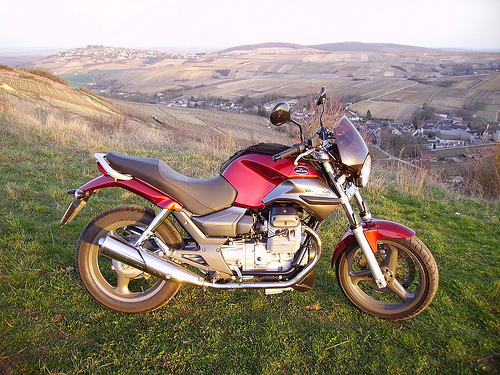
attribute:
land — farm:
[28, 45, 490, 152]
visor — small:
[330, 112, 369, 171]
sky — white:
[96, 0, 373, 71]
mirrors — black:
[269, 84, 327, 131]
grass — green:
[235, 307, 363, 358]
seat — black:
[106, 147, 238, 217]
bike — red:
[58, 85, 439, 321]